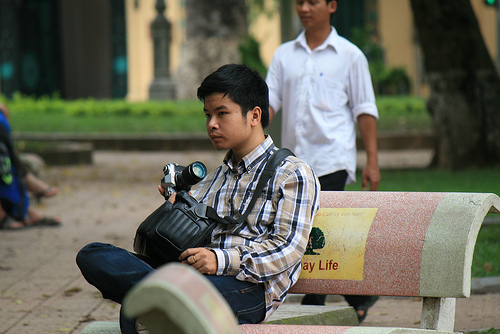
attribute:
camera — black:
[152, 154, 214, 204]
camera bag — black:
[129, 201, 241, 255]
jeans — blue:
[74, 238, 270, 320]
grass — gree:
[20, 95, 182, 137]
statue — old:
[142, 2, 178, 79]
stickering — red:
[372, 192, 442, 301]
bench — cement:
[116, 183, 499, 333]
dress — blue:
[4, 120, 37, 224]